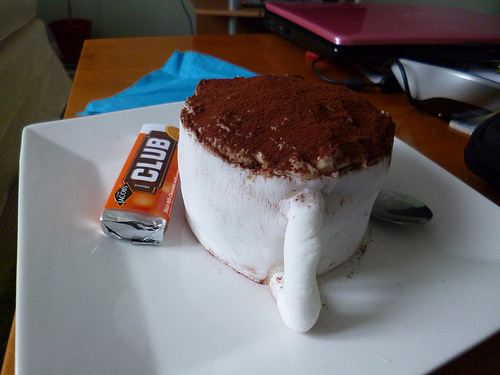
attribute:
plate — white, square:
[14, 100, 499, 374]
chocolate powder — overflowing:
[182, 71, 396, 186]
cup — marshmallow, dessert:
[178, 75, 394, 332]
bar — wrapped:
[99, 123, 181, 245]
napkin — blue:
[77, 51, 260, 117]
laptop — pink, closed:
[263, 0, 500, 66]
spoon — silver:
[371, 187, 434, 226]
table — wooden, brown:
[1, 33, 500, 374]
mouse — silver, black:
[391, 55, 500, 119]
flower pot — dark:
[47, 17, 91, 64]